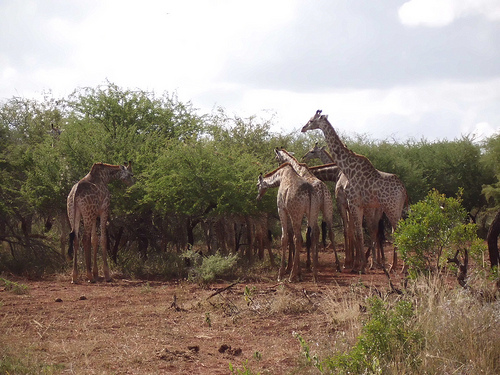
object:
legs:
[70, 217, 78, 271]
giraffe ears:
[318, 115, 325, 121]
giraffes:
[302, 110, 407, 275]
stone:
[216, 343, 244, 357]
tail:
[65, 194, 79, 260]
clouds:
[388, 0, 458, 29]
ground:
[1, 233, 500, 373]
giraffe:
[307, 162, 341, 183]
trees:
[0, 82, 500, 259]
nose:
[301, 127, 306, 131]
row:
[2, 77, 498, 265]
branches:
[208, 281, 248, 316]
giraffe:
[66, 162, 136, 286]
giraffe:
[257, 163, 334, 281]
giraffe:
[301, 143, 384, 273]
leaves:
[0, 79, 500, 284]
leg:
[85, 218, 93, 277]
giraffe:
[270, 147, 345, 274]